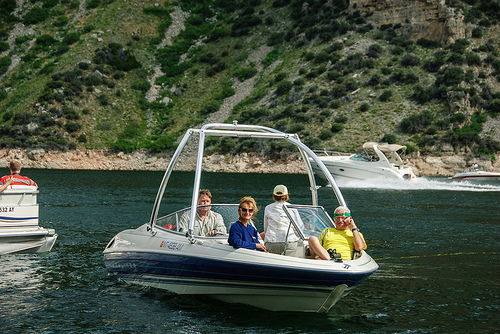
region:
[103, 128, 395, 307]
four people in a boat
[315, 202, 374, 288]
man in a yellow shirt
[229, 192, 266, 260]
person in a blue shirt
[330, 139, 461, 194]
boat creating a wake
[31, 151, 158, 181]
water and rocky shoreline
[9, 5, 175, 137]
green foliage on hillside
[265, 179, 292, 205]
back of head wearing a hat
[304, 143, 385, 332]
man sitting in bow of boat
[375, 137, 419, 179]
shade awning on small boat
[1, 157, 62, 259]
back of a boat in water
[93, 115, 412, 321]
power boat on water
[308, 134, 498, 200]
motor boat leaving wake in water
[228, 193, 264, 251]
woman wearing blue jacket and sunglasses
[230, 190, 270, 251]
woman smiling at camera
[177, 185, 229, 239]
man steering boat in water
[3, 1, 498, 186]
rocky shoreline below hill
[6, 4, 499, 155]
hill covered with vegetation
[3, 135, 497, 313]
boats on dark water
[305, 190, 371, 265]
man in yellow shirt and shorts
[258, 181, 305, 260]
person wearing baseball cap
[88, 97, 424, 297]
Four people enjoying a boat ride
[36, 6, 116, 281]
A river in foothills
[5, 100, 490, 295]
Four motorboats in river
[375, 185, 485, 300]
Calm river water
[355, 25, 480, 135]
Small bushes on the hill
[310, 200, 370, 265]
A man wearing a yellow t-shirt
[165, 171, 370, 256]
Four people in the boat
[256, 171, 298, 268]
A woman facing the hill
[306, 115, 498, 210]
Motorboat going fast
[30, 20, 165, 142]
Green grass and bushes on the hill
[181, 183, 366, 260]
People are on a boat.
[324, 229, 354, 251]
The man's shirt is yellow.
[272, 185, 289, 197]
The woman wears a cap.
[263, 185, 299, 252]
The back of the woman is visible.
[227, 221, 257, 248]
The woman's top is blue.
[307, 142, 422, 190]
A boat is in the background.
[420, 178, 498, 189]
The boat creates a trail in the water.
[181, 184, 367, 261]
The boat carries four people.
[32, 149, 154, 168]
The shore is rocky.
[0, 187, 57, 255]
A third boat is on the left.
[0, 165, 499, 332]
The water is green.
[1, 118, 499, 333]
Boats are in the water.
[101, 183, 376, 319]
People are in the boat.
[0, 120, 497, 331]
Four boats are in the water.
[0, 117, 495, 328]
The boats are white.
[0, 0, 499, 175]
A hill is in the background.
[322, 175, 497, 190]
The boat is making waves.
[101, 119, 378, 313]
The boats has bars on it.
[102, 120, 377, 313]
The bars are gray.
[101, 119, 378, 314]
The bars are made of metal.